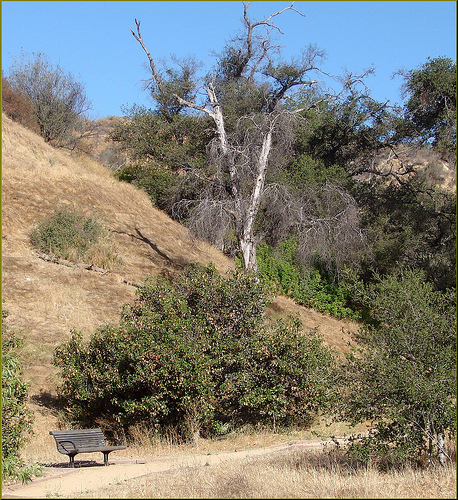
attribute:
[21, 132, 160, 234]
hill — steep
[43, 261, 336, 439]
bushy tree — bushy 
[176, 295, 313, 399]
tree — bushy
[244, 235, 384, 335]
shrubbery — bright green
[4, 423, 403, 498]
dirt path — long, narrow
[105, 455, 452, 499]
vegetation — dried out, sunburnt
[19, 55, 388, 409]
mountain — steep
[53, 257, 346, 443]
bush — green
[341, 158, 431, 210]
tree — bushy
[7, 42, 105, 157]
tree — bushy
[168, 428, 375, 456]
path — dirt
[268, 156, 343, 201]
leaves — dry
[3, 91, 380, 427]
hillside — dirt covered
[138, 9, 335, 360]
tree — tall, dead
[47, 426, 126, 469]
bench — brown, wooden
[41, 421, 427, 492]
walk wau — dirt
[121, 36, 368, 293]
tree — bushy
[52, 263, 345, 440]
shrubbery — green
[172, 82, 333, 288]
tree — dead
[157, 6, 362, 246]
trees — dead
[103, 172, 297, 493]
bush — green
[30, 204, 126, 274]
tree — bushy 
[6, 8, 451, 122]
skies — blue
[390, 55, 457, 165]
tree — bushy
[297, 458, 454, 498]
grass — dry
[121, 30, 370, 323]
tree — brown